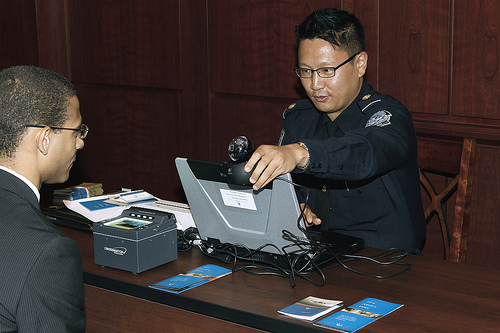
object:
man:
[1, 65, 90, 333]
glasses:
[25, 124, 89, 139]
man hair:
[0, 66, 77, 158]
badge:
[365, 110, 393, 128]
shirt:
[278, 82, 428, 254]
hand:
[244, 143, 308, 191]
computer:
[174, 157, 366, 268]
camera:
[227, 135, 255, 163]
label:
[219, 188, 257, 210]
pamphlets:
[312, 297, 404, 333]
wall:
[1, 0, 500, 269]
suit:
[1, 168, 89, 333]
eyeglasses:
[294, 51, 363, 78]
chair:
[413, 138, 478, 263]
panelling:
[70, 0, 184, 200]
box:
[93, 206, 178, 275]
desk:
[42, 184, 500, 333]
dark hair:
[294, 7, 366, 65]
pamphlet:
[147, 264, 233, 295]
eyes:
[323, 68, 331, 72]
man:
[243, 7, 427, 254]